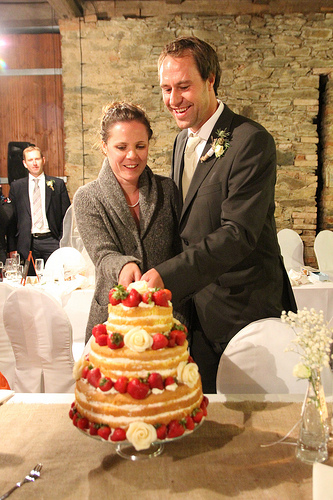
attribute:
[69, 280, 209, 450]
cake — brown,white, red, frosted, three tiered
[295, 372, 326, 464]
vase — clear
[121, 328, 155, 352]
rose — white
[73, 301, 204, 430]
filling — white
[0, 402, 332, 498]
table runner — tan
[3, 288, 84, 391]
chair cover — white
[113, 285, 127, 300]
stem — green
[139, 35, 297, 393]
man — smiling, light skinned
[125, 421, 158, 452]
rose — white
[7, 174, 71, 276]
suit — black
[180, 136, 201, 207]
tie — white